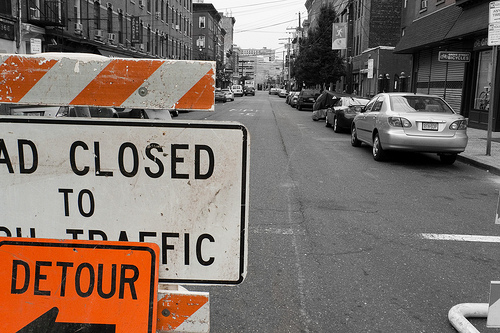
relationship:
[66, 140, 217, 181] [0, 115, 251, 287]
word on sign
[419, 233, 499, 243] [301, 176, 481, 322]
line on road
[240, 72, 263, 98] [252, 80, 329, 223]
bus far on road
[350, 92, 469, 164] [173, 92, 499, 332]
car parked on street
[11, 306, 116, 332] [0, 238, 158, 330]
arrow on sign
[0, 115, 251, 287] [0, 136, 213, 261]
sign with lettering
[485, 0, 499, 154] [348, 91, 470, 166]
sign beside car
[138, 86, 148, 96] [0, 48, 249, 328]
bolt on traffic barrier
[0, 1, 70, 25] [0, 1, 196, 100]
balcony on building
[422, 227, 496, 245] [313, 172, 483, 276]
line painted on ground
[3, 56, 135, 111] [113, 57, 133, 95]
specks in orange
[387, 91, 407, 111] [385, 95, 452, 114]
light shining on window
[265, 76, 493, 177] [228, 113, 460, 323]
cars parked on side of road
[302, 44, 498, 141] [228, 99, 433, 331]
shops along road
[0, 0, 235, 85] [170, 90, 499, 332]
buildings next to road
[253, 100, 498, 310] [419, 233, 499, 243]
street paved with line